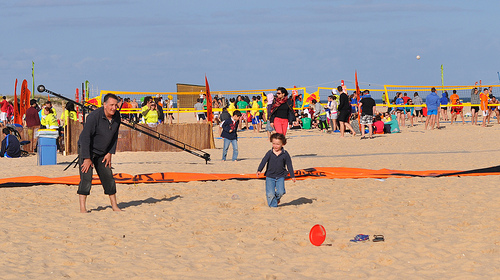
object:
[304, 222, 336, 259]
frisbee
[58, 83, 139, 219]
man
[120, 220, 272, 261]
sand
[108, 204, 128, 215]
foot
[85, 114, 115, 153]
gray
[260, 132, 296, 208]
boy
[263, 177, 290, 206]
jeans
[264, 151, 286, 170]
gray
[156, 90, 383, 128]
people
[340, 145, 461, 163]
beach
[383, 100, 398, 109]
yellow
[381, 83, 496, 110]
nets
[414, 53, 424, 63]
volleyball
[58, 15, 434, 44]
sky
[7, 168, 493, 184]
banner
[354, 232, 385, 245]
sandals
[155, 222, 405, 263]
ground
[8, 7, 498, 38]
air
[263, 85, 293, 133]
woman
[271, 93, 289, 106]
scarf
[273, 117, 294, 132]
pants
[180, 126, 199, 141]
section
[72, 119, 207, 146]
fence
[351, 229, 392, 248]
flipflops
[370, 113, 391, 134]
person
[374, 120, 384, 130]
shirt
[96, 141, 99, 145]
over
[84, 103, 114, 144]
shirt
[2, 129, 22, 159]
person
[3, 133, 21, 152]
shirt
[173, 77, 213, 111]
building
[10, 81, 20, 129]
flag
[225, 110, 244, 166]
child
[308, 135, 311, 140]
brown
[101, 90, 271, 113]
net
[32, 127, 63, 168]
trashcan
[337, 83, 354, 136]
man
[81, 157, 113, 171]
hands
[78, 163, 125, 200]
legs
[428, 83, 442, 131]
man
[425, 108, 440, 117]
shorts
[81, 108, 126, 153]
sweater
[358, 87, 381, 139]
person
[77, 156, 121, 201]
jeans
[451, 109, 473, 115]
shorts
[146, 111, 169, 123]
shirt